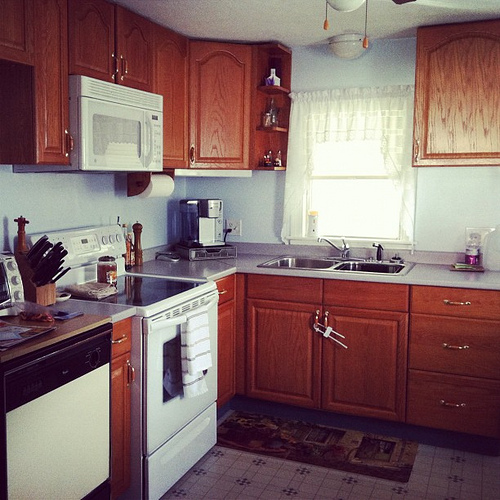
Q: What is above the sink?
A: Window.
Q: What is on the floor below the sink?
A: Rug.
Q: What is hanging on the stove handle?
A: Towel.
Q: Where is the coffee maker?
A: On counter in corner.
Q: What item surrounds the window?
A: White curtains.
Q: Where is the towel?
A: Hanging from the oven door handle.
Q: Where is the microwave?
A: Above the stove.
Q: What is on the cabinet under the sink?
A: Child-proof lock.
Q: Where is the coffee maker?
A: In the corner on the cabinet.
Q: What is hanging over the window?
A: A white curtain.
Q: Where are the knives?
A: In the knife rack to the left of the stove.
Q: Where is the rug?
A: Below the sink.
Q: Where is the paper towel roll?
A: Hanging beneath the cabinet to the right of the stove.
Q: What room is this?
A: Kitchen.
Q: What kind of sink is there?
A: A double basin steel sink.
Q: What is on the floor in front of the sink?
A: Rug.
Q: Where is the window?
A: Above the sink.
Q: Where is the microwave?
A: Above the stove.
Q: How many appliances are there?
A: Five.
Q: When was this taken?
A: During the day.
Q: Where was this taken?
A: In a kitchen.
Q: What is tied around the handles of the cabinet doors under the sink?
A: A safety tie.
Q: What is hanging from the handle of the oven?
A: A dish towel.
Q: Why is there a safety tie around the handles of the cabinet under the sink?
A: To prevent children from getting inside.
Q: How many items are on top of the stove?
A: Two.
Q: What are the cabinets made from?
A: Wood.